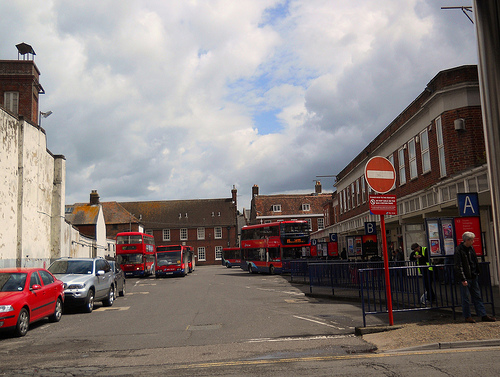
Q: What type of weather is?
A: It is cloudy.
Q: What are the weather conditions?
A: It is cloudy.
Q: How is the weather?
A: It is cloudy.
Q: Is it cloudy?
A: Yes, it is cloudy.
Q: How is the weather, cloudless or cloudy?
A: It is cloudy.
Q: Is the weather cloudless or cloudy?
A: It is cloudy.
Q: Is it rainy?
A: No, it is cloudy.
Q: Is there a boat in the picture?
A: No, there are no boats.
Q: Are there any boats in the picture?
A: No, there are no boats.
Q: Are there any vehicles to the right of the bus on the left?
A: Yes, there is a vehicle to the right of the bus.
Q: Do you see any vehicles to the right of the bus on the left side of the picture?
A: Yes, there is a vehicle to the right of the bus.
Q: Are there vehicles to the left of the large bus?
A: No, the vehicle is to the right of the bus.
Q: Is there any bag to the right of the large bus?
A: No, there is a vehicle to the right of the bus.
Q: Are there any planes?
A: No, there are no planes.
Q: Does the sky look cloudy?
A: Yes, the sky is cloudy.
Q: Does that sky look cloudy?
A: Yes, the sky is cloudy.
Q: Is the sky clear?
A: No, the sky is cloudy.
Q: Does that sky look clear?
A: No, the sky is cloudy.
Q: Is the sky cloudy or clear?
A: The sky is cloudy.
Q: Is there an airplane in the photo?
A: No, there are no airplanes.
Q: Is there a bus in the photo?
A: Yes, there is a bus.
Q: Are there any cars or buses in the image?
A: Yes, there is a bus.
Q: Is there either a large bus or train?
A: Yes, there is a large bus.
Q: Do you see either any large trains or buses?
A: Yes, there is a large bus.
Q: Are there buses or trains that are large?
A: Yes, the bus is large.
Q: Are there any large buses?
A: Yes, there is a large bus.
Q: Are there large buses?
A: Yes, there is a large bus.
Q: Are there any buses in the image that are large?
A: Yes, there is a bus that is large.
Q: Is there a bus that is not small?
A: Yes, there is a large bus.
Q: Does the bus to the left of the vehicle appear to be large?
A: Yes, the bus is large.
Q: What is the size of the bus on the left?
A: The bus is large.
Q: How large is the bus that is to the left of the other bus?
A: The bus is large.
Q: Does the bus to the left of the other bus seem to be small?
A: No, the bus is large.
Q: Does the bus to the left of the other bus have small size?
A: No, the bus is large.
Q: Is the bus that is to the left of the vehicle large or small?
A: The bus is large.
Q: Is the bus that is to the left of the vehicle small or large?
A: The bus is large.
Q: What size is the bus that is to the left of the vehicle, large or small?
A: The bus is large.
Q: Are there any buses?
A: Yes, there are buses.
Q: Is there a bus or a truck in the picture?
A: Yes, there are buses.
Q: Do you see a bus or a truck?
A: Yes, there are buses.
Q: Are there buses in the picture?
A: Yes, there is a bus.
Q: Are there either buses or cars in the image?
A: Yes, there is a bus.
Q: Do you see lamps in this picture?
A: No, there are no lamps.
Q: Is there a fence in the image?
A: Yes, there is a fence.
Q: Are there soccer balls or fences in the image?
A: Yes, there is a fence.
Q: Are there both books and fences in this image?
A: No, there is a fence but no books.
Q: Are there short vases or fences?
A: Yes, there is a short fence.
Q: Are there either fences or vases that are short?
A: Yes, the fence is short.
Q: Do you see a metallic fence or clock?
A: Yes, there is a metal fence.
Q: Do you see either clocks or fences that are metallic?
A: Yes, the fence is metallic.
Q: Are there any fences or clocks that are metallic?
A: Yes, the fence is metallic.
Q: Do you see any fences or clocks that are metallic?
A: Yes, the fence is metallic.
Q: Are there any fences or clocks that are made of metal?
A: Yes, the fence is made of metal.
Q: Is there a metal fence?
A: Yes, there is a fence that is made of metal.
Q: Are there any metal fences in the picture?
A: Yes, there is a fence that is made of metal.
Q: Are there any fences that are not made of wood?
A: Yes, there is a fence that is made of metal.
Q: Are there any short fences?
A: Yes, there is a short fence.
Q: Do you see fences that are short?
A: Yes, there is a fence that is short.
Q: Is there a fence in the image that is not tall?
A: Yes, there is a short fence.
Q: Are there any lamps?
A: No, there are no lamps.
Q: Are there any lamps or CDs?
A: No, there are no lamps or cds.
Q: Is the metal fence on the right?
A: Yes, the fence is on the right of the image.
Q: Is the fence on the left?
A: No, the fence is on the right of the image.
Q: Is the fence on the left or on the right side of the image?
A: The fence is on the right of the image.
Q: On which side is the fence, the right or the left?
A: The fence is on the right of the image.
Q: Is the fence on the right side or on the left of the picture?
A: The fence is on the right of the image.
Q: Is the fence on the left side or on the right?
A: The fence is on the right of the image.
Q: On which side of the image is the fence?
A: The fence is on the right of the image.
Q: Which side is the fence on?
A: The fence is on the right of the image.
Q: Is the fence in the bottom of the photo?
A: Yes, the fence is in the bottom of the image.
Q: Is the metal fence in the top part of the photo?
A: No, the fence is in the bottom of the image.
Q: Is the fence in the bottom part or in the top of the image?
A: The fence is in the bottom of the image.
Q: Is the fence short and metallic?
A: Yes, the fence is short and metallic.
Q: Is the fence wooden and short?
A: No, the fence is short but metallic.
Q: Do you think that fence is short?
A: Yes, the fence is short.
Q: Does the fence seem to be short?
A: Yes, the fence is short.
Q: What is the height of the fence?
A: The fence is short.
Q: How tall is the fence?
A: The fence is short.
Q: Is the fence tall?
A: No, the fence is short.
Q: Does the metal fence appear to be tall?
A: No, the fence is short.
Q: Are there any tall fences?
A: No, there is a fence but it is short.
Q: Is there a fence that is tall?
A: No, there is a fence but it is short.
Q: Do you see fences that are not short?
A: No, there is a fence but it is short.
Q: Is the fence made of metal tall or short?
A: The fence is short.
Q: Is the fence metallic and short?
A: Yes, the fence is metallic and short.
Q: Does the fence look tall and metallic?
A: No, the fence is metallic but short.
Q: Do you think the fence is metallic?
A: Yes, the fence is metallic.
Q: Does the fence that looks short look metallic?
A: Yes, the fence is metallic.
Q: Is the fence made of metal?
A: Yes, the fence is made of metal.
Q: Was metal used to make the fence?
A: Yes, the fence is made of metal.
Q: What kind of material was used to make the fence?
A: The fence is made of metal.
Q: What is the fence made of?
A: The fence is made of metal.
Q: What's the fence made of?
A: The fence is made of metal.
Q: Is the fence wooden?
A: No, the fence is metallic.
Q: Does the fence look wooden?
A: No, the fence is metallic.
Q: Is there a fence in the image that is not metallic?
A: No, there is a fence but it is metallic.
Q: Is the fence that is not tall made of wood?
A: No, the fence is made of metal.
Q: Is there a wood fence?
A: No, there is a fence but it is made of metal.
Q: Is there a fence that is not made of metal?
A: No, there is a fence but it is made of metal.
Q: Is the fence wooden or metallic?
A: The fence is metallic.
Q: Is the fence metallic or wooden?
A: The fence is metallic.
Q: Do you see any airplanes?
A: No, there are no airplanes.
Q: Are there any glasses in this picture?
A: No, there are no glasses.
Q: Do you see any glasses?
A: No, there are no glasses.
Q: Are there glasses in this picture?
A: No, there are no glasses.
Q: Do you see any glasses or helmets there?
A: No, there are no glasses or helmets.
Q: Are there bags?
A: No, there are no bags.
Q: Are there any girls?
A: No, there are no girls.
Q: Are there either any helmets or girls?
A: No, there are no girls or helmets.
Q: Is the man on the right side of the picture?
A: Yes, the man is on the right of the image.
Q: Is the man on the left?
A: No, the man is on the right of the image.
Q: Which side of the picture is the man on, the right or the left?
A: The man is on the right of the image.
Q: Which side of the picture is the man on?
A: The man is on the right of the image.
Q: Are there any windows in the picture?
A: Yes, there is a window.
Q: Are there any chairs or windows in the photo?
A: Yes, there is a window.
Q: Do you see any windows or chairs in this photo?
A: Yes, there is a window.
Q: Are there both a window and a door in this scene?
A: No, there is a window but no doors.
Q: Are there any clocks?
A: No, there are no clocks.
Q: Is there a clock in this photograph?
A: No, there are no clocks.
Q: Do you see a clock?
A: No, there are no clocks.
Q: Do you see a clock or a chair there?
A: No, there are no clocks or chairs.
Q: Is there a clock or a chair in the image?
A: No, there are no clocks or chairs.